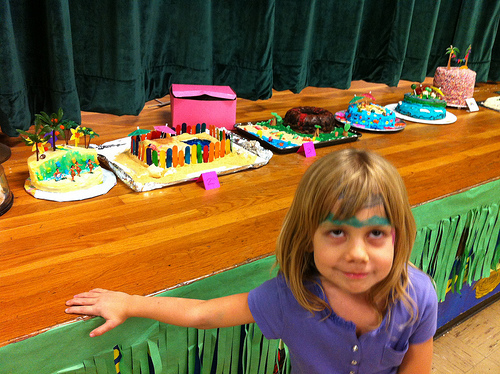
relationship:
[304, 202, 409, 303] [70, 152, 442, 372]
face of child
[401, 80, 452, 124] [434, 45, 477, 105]
blue cake next to cakes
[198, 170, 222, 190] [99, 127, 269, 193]
note near cake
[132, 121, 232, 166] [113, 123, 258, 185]
fence on top of cake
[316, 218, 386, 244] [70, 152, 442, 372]
eyes of child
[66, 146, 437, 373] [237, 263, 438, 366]
child wearing a shirt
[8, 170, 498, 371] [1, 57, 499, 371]
fringe on table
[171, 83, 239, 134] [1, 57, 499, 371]
box on table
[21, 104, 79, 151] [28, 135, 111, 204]
trees on top of a cake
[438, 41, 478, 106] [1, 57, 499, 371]
cakes on table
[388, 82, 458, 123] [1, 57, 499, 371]
cakes on table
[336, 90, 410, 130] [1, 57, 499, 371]
cakes on table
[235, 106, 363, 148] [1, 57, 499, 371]
cakes on table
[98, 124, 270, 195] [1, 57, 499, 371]
cakes on table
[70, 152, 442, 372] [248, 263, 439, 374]
child wearing a purple shirt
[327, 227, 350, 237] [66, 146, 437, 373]
eyes of a child